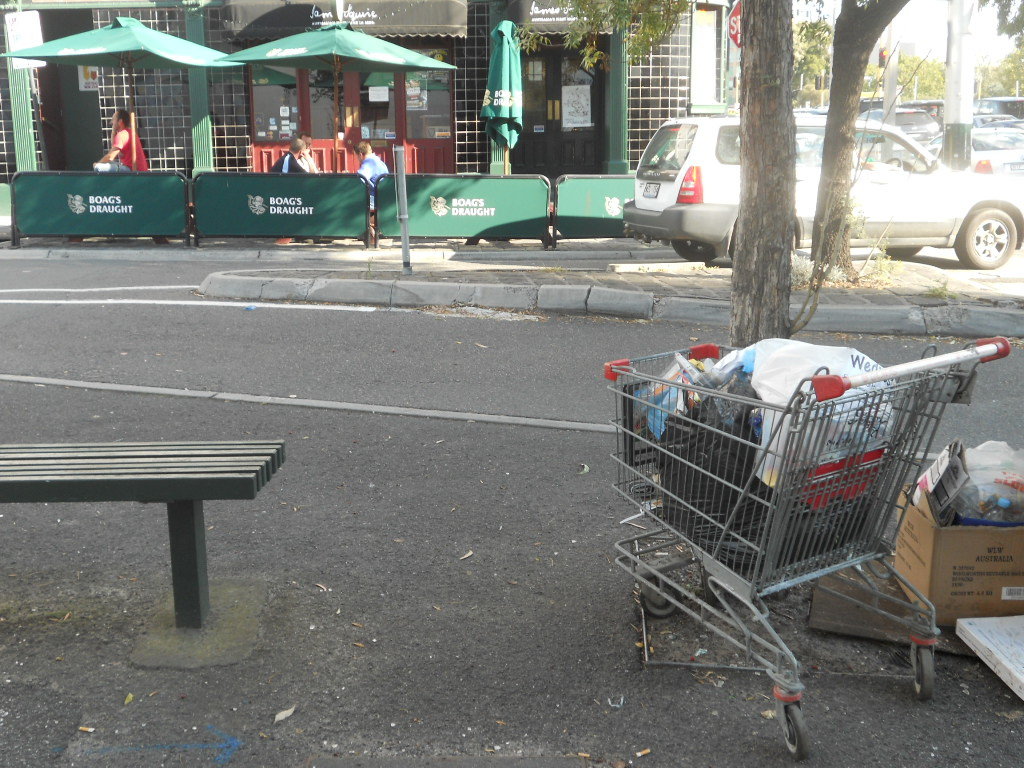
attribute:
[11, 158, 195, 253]
barricade — green and white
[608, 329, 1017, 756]
shopping cart — full, red, silver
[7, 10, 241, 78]
umbrella — large, green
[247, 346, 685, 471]
line — white, road markings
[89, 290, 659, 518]
road — gray, paved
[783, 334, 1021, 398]
handle — thin, smooth, white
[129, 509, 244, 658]
bench leg — the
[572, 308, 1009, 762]
cart — metal, wire, wheeled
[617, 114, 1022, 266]
automobile — white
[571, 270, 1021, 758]
cart — gray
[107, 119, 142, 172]
shirt — red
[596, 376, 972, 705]
shopping cart — silver, wire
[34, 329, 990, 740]
pavement — gray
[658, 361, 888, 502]
merchandise — pleasing, economical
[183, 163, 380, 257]
barricade — green and white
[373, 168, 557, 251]
barricade — green and white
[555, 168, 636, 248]
barricade — green and white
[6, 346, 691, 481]
view — a